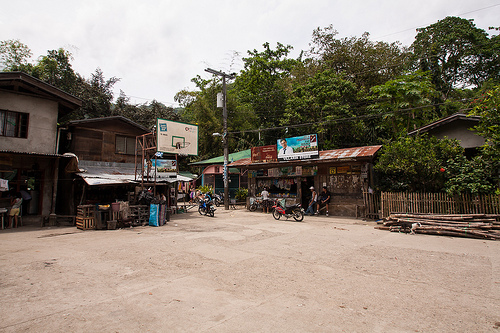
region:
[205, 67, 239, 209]
wooden utility pole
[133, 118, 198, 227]
homemade basketball hoop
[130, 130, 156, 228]
basketball hoop stand made of rusted pipe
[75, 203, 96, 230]
wooden crates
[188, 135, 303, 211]
retail shops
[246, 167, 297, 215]
man buying at outdoor market stall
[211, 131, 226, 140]
exterior light fixture mounted on utility pole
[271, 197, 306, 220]
red and black motorcycle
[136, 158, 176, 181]
roof-mounted advertising billboard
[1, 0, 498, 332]
rural village market buildings with outdoor stalls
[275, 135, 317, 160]
Sign featuring man in shirt and tie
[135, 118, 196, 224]
Aged basketball hoop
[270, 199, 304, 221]
Red and black motorcycle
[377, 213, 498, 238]
Large stack of wood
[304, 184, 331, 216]
Two men sitting on cement wall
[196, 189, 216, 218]
Man in blue riding bicycle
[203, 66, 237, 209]
Tall wooden telephone pole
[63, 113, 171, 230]
Two story wooden house surrounded by clutter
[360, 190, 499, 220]
Wooden house separating house from street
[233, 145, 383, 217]
Single story storefront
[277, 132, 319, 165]
Colorful billboard on metal roof of building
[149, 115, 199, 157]
Basketball net and backboard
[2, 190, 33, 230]
Person wearing yellow shorts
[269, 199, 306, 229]
Red and black motorbike parked next to building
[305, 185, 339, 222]
Two people sitting on bench next to store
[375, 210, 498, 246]
Cut logs laying on ground by fence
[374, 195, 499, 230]
Wooden picket fence behind logs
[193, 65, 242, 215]
Telephone pole in front of building with green roof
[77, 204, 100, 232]
Wooden crates stacked on side of road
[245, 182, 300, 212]
Man standing at table with items for sale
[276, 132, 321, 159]
a sign with a person's face on it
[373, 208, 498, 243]
a pile of logs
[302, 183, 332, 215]
two guys sitting in front of the store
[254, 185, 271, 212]
a person standing at a counter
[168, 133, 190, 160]
a basketball hoop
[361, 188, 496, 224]
a wooden fence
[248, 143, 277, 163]
a red sign on top of the building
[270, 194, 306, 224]
a red moped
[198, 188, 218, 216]
a blue moped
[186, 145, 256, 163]
a green roof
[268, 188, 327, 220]
small motorcycle on dirt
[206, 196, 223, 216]
small motorcycle on dirt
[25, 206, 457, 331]
dirt field by buildings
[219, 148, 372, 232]
small shacks on right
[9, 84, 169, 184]
wooden buildings on left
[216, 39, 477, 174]
trees growing behind buildings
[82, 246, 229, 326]
tracks on dirt ground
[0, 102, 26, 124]
small window in building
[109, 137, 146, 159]
small window in building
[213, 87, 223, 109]
transformer on wooden pole